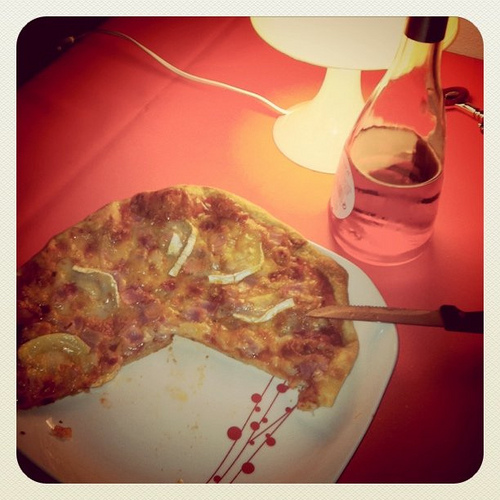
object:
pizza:
[16, 183, 359, 409]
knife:
[304, 303, 483, 334]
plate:
[17, 238, 399, 490]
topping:
[17, 332, 89, 357]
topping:
[232, 297, 295, 325]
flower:
[206, 375, 298, 483]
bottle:
[326, 17, 448, 268]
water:
[331, 126, 441, 264]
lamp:
[248, 17, 458, 173]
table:
[16, 17, 482, 484]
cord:
[91, 27, 287, 115]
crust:
[207, 190, 321, 266]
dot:
[225, 424, 243, 441]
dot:
[250, 391, 262, 404]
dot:
[276, 382, 290, 395]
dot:
[240, 460, 256, 477]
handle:
[438, 305, 483, 332]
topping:
[166, 217, 198, 279]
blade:
[306, 305, 442, 326]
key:
[443, 86, 483, 129]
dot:
[265, 437, 276, 447]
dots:
[226, 393, 275, 475]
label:
[331, 150, 355, 220]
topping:
[73, 264, 121, 305]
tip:
[305, 307, 339, 321]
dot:
[283, 405, 292, 415]